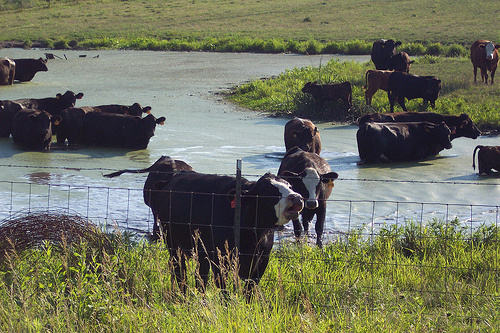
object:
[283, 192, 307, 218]
mouth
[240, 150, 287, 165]
shadow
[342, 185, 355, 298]
wire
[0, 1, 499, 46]
field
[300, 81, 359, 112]
calf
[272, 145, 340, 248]
cow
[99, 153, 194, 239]
cow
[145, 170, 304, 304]
cow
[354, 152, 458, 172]
shadow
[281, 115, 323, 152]
cattle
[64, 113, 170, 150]
cattle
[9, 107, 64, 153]
cattle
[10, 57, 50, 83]
cattle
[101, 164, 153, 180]
tail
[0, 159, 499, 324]
fence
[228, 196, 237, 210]
tag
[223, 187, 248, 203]
ear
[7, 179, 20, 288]
wire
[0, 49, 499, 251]
water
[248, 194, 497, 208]
wire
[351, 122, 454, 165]
cow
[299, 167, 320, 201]
stripe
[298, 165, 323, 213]
face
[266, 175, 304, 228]
face